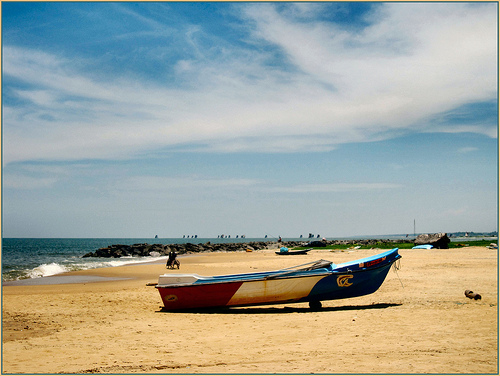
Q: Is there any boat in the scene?
A: Yes, there is a boat.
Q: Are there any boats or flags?
A: Yes, there is a boat.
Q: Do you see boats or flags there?
A: Yes, there is a boat.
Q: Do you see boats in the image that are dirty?
A: Yes, there is a dirty boat.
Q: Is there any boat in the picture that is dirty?
A: Yes, there is a boat that is dirty.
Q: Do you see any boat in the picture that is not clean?
A: Yes, there is a dirty boat.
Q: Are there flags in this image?
A: No, there are no flags.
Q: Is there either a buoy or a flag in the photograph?
A: No, there are no flags or buoys.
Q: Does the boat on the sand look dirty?
A: Yes, the boat is dirty.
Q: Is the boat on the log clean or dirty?
A: The boat is dirty.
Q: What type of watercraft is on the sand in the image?
A: The watercraft is a boat.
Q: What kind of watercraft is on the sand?
A: The watercraft is a boat.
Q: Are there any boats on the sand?
A: Yes, there is a boat on the sand.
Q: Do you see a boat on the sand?
A: Yes, there is a boat on the sand.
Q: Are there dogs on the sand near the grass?
A: No, there is a boat on the sand.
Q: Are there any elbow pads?
A: No, there are no elbow pads.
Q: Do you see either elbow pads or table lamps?
A: No, there are no elbow pads or table lamps.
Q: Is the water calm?
A: Yes, the water is calm.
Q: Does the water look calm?
A: Yes, the water is calm.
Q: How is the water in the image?
A: The water is calm.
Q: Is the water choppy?
A: No, the water is calm.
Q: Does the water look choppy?
A: No, the water is calm.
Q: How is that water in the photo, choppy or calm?
A: The water is calm.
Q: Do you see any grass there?
A: Yes, there is grass.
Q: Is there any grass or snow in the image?
A: Yes, there is grass.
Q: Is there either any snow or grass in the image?
A: Yes, there is grass.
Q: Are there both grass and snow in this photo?
A: No, there is grass but no snow.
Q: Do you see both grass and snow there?
A: No, there is grass but no snow.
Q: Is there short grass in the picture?
A: Yes, there is short grass.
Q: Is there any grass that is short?
A: Yes, there is grass that is short.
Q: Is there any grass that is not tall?
A: Yes, there is short grass.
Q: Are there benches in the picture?
A: No, there are no benches.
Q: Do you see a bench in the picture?
A: No, there are no benches.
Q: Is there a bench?
A: No, there are no benches.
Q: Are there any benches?
A: No, there are no benches.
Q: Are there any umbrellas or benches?
A: No, there are no benches or umbrellas.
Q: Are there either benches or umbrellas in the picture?
A: No, there are no benches or umbrellas.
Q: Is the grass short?
A: Yes, the grass is short.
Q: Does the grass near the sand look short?
A: Yes, the grass is short.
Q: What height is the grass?
A: The grass is short.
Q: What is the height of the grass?
A: The grass is short.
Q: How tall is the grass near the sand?
A: The grass is short.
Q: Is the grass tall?
A: No, the grass is short.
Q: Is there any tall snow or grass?
A: No, there is grass but it is short.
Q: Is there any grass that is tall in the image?
A: No, there is grass but it is short.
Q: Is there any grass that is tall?
A: No, there is grass but it is short.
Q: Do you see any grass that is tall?
A: No, there is grass but it is short.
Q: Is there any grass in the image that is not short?
A: No, there is grass but it is short.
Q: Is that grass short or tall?
A: The grass is short.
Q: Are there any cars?
A: No, there are no cars.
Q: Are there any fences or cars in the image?
A: No, there are no cars or fences.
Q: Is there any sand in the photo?
A: Yes, there is sand.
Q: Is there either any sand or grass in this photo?
A: Yes, there is sand.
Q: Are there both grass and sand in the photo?
A: Yes, there are both sand and grass.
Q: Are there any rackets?
A: No, there are no rackets.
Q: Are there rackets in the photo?
A: No, there are no rackets.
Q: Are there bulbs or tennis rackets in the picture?
A: No, there are no tennis rackets or bulbs.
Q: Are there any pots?
A: No, there are no pots.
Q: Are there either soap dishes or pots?
A: No, there are no pots or soap dishes.